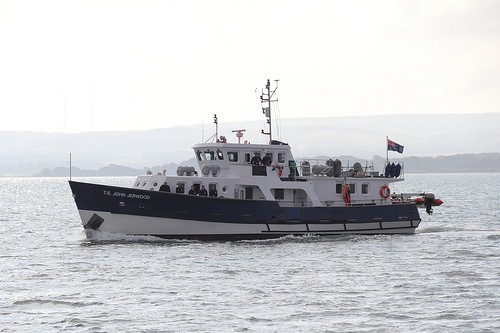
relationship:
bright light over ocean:
[75, 9, 323, 79] [112, 250, 359, 311]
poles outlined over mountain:
[52, 88, 86, 140] [1, 101, 183, 176]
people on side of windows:
[158, 179, 219, 199] [145, 169, 242, 209]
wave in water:
[9, 292, 104, 314] [0, 171, 499, 332]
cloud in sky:
[62, 39, 232, 89] [1, 0, 499, 128]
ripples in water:
[428, 221, 492, 252] [0, 171, 499, 332]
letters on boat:
[103, 189, 150, 199] [68, 142, 420, 239]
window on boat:
[348, 183, 367, 194] [55, 69, 454, 291]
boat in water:
[51, 90, 448, 243] [0, 171, 499, 332]